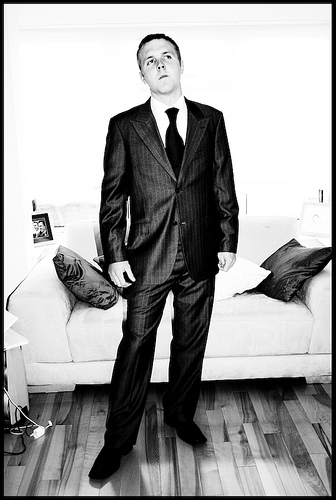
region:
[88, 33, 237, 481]
the man standing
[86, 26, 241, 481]
the man standing in a suit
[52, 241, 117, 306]
the pillow on the couch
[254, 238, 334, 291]
the pillow on the sofa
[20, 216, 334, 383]
the couch behind the man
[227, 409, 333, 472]
the wooden flooring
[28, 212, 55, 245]
the picture frame near the couch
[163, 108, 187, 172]
the man's tie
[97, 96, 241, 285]
the man's jacket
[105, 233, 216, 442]
the man's long pants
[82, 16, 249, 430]
the man is wearing a suit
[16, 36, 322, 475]
the picture is black and white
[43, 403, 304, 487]
the floors are made of wood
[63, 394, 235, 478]
the man is wearing black shoes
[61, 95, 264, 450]
the suit is pin striped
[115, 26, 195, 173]
the man is wearing a tie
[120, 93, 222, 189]
the tie is black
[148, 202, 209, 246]
the button is undone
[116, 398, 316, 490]
the floor is mixed wood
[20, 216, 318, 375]
the couch is white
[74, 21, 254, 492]
person wearing a suit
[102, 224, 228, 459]
person wearing striped pants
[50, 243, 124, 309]
pillow on a couch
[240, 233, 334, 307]
pillow on a couch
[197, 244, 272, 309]
pillow on a couch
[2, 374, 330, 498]
floor made of hardwood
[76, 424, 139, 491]
black shoe on a foot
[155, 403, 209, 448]
black shoe on a foot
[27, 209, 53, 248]
picture in a frame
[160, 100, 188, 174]
black tie on a person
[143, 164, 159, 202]
stripes on man's suit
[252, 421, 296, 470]
part of the flooring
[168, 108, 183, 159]
tie worn by man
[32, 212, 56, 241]
picture in small frame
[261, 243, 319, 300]
dark pillow on sofa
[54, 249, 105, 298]
printed pillow on couch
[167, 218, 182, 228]
button on man's suit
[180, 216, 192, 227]
button hole on suit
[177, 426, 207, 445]
shoe on man's foot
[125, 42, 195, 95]
face of the man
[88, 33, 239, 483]
a young man standing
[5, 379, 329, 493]
a tiled hardwood floor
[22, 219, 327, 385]
a light colored love seat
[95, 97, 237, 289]
a shiny dark suit coat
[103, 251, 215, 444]
shiny black suit pants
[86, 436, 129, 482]
a black right shoe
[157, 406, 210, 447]
a black left shoe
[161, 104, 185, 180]
a dark colored tie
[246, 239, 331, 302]
a dark colored pillow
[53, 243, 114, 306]
a dark colored pillow